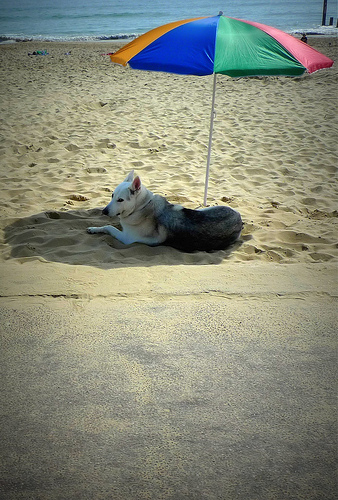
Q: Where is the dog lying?
A: In the sand.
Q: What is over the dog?
A: A beach umbrella.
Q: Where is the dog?
A: On the beach.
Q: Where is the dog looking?
A: Left.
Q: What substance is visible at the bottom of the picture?
A: Water.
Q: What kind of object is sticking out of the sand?
A: Umbrella.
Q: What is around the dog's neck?
A: Collar.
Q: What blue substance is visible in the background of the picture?
A: Water.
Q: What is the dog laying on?
A: Sand.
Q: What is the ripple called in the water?
A: A wave.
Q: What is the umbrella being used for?
A: Shade.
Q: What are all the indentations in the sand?
A: Footprints.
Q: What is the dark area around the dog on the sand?
A: Shadow.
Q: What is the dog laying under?
A: Open umbrella.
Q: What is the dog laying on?
A: Sand.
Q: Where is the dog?
A: At the beach.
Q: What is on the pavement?
A: Sand.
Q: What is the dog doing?
A: Laying down.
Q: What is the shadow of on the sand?
A: The umbrella.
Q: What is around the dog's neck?
A: Collar.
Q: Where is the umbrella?
A: On the beach.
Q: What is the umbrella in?
A: Sand.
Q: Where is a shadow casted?
A: Under umbrella.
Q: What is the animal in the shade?
A: A dog.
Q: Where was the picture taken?
A: The beach.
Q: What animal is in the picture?
A: A dog.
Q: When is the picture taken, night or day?
A: During the day.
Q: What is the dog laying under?
A: An umbrella.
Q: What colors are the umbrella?
A: Orange, Blue, Green and Pink.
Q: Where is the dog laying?
A: In the sand.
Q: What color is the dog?
A: Black and white.